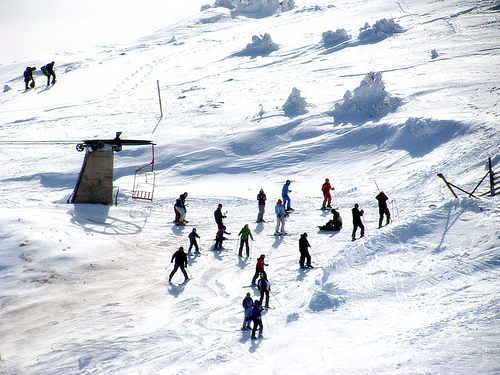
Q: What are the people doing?
A: Getting reading to ski.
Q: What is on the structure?
A: A chair lift.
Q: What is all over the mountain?
A: Snow.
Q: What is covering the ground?
A: Snow.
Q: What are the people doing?
A: Skiing.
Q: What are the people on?
A: Mountain.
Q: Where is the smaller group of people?
A: Top left.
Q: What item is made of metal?
A: Ski lift.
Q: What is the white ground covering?
A: Snow.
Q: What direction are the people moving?
A: Up the mountain.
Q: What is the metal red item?
A: Ski lift.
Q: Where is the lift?
A: Stuck in the snow.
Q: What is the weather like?
A: Snow.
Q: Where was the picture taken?
A: At a ski slope.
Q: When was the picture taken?
A: Daytime.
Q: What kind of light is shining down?
A: Sunlight.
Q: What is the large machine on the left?
A: A ski lift.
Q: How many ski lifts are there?
A: One.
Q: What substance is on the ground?
A: Snow.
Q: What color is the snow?
A: White.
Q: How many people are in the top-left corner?
A: Two.